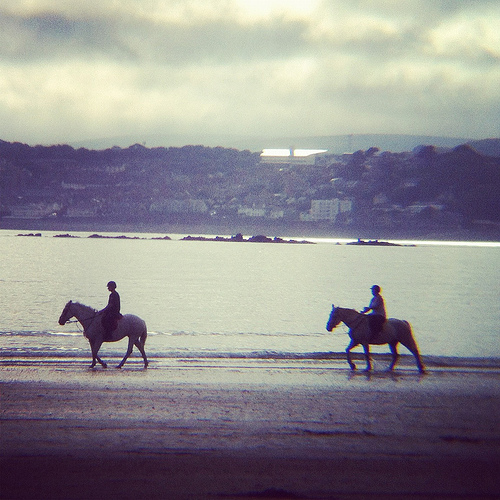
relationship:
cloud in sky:
[308, 15, 419, 58] [1, 0, 498, 150]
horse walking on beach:
[60, 300, 153, 372] [3, 360, 498, 498]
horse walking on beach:
[326, 301, 426, 376] [3, 360, 498, 498]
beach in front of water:
[3, 360, 498, 498] [0, 228, 499, 353]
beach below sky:
[3, 360, 498, 498] [1, 0, 498, 150]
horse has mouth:
[60, 300, 153, 372] [59, 317, 66, 324]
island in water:
[335, 239, 413, 247] [0, 228, 499, 353]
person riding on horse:
[94, 281, 121, 341] [60, 300, 153, 372]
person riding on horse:
[357, 285, 388, 341] [326, 301, 426, 376]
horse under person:
[60, 300, 153, 372] [94, 281, 121, 341]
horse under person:
[326, 301, 426, 376] [357, 285, 388, 341]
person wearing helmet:
[94, 281, 121, 341] [107, 281, 117, 287]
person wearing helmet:
[357, 285, 388, 341] [370, 284, 380, 292]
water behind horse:
[0, 228, 499, 353] [60, 300, 153, 372]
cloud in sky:
[0, 11, 140, 65] [1, 0, 498, 150]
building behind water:
[300, 200, 354, 225] [0, 228, 499, 353]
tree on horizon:
[242, 148, 250, 156] [1, 125, 498, 160]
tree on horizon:
[366, 145, 380, 156] [1, 125, 498, 160]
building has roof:
[259, 148, 331, 166] [257, 149, 329, 157]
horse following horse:
[326, 301, 426, 376] [60, 300, 153, 372]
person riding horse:
[94, 281, 121, 341] [60, 300, 153, 372]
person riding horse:
[357, 285, 388, 341] [326, 301, 426, 376]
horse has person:
[60, 300, 153, 372] [94, 281, 121, 341]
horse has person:
[326, 301, 426, 376] [357, 285, 388, 341]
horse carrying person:
[60, 300, 153, 372] [94, 281, 121, 341]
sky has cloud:
[1, 0, 498, 150] [45, 84, 97, 121]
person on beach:
[94, 281, 121, 341] [3, 360, 498, 498]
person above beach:
[357, 285, 388, 341] [3, 360, 498, 498]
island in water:
[179, 235, 320, 245] [0, 228, 499, 353]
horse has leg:
[60, 300, 153, 372] [92, 336, 109, 369]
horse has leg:
[60, 300, 153, 372] [90, 339, 113, 369]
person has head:
[94, 281, 121, 341] [106, 281, 117, 292]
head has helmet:
[106, 281, 117, 292] [107, 281, 117, 287]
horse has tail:
[60, 300, 153, 372] [140, 321, 148, 351]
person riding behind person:
[357, 285, 388, 341] [94, 281, 121, 341]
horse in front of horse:
[60, 300, 153, 372] [326, 301, 426, 376]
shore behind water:
[0, 200, 498, 241] [0, 228, 499, 353]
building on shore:
[300, 200, 354, 225] [0, 200, 498, 241]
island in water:
[86, 232, 175, 240] [0, 228, 499, 353]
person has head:
[357, 285, 388, 341] [370, 284, 382, 296]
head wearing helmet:
[370, 284, 382, 296] [370, 284, 380, 292]